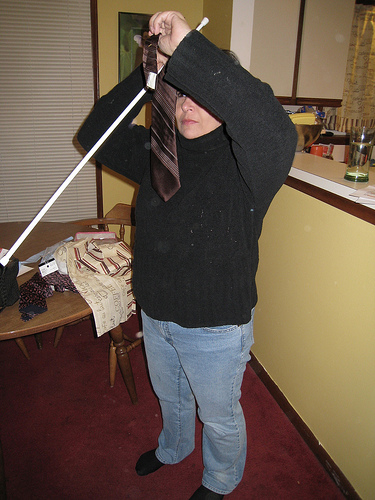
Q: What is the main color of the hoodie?
A: Black.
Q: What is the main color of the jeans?
A: Blue.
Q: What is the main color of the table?
A: Brown.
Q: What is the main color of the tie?
A: Brown.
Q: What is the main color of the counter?
A: White.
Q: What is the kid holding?
A: Dad's tie.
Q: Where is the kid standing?
A: Carpet.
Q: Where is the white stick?
A: On the kid.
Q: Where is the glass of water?
A: On the counter.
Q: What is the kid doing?
A: Tying a tie.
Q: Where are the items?
A: On top of dining table.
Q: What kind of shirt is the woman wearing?
A: Black sweater.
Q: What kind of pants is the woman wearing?
A: Jeans.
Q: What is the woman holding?
A: A tie.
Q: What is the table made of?
A: Wood.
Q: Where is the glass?
A: On the counter.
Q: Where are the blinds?
A: On the window.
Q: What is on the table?
A: Clothes.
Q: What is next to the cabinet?
A: Curtain.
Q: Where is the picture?
A: Behind the woman.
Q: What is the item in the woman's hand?
A: Tie.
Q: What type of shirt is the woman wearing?
A: Sweater.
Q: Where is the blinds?
A: Window.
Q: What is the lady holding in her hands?
A: A stick and a tie.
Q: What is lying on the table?
A: Clothes.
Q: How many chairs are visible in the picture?
A: One.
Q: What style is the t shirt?
A: Polo-neck.